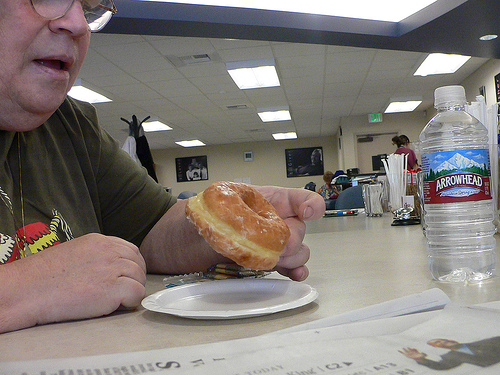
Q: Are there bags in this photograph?
A: No, there are no bags.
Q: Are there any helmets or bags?
A: No, there are no bags or helmets.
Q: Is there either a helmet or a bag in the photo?
A: No, there are no bags or helmets.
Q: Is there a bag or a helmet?
A: No, there are no bags or helmets.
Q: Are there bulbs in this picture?
A: No, there are no bulbs.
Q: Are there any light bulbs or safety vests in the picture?
A: No, there are no light bulbs or safety vests.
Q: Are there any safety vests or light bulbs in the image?
A: No, there are no light bulbs or safety vests.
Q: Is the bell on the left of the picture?
A: No, the bell is on the right of the image.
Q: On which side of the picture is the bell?
A: The bell is on the right of the image.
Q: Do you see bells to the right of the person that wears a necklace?
A: Yes, there is a bell to the right of the person.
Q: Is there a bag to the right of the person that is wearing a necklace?
A: No, there is a bell to the right of the person.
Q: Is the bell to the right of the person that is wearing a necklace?
A: Yes, the bell is to the right of the person.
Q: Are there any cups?
A: Yes, there is a cup.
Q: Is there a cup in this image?
A: Yes, there is a cup.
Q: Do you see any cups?
A: Yes, there is a cup.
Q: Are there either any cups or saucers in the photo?
A: Yes, there is a cup.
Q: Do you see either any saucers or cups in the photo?
A: Yes, there is a cup.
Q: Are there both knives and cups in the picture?
A: No, there is a cup but no knives.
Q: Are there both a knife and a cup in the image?
A: No, there is a cup but no knives.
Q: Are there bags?
A: No, there are no bags.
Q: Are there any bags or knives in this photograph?
A: No, there are no bags or knives.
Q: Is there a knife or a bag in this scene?
A: No, there are no bags or knives.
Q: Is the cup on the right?
A: Yes, the cup is on the right of the image.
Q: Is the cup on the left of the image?
A: No, the cup is on the right of the image.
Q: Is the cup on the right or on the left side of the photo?
A: The cup is on the right of the image.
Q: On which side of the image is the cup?
A: The cup is on the right of the image.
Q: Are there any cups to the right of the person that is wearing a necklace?
A: Yes, there is a cup to the right of the person.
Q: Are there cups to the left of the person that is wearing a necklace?
A: No, the cup is to the right of the person.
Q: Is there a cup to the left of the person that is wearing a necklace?
A: No, the cup is to the right of the person.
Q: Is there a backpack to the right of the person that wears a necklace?
A: No, there is a cup to the right of the person.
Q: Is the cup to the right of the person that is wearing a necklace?
A: Yes, the cup is to the right of the person.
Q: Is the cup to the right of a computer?
A: No, the cup is to the right of the person.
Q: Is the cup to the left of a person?
A: No, the cup is to the right of a person.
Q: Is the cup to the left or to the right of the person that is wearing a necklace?
A: The cup is to the right of the person.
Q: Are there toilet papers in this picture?
A: No, there are no toilet papers.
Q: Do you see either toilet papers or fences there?
A: No, there are no toilet papers or fences.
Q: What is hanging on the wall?
A: The poster is hanging on the wall.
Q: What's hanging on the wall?
A: The poster is hanging on the wall.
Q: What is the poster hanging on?
A: The poster is hanging on the wall.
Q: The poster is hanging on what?
A: The poster is hanging on the wall.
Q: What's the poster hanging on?
A: The poster is hanging on the wall.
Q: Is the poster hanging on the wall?
A: Yes, the poster is hanging on the wall.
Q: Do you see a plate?
A: Yes, there is a plate.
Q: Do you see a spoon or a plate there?
A: Yes, there is a plate.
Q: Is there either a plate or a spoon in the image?
A: Yes, there is a plate.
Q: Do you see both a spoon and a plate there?
A: No, there is a plate but no spoons.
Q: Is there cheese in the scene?
A: No, there is no cheese.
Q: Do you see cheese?
A: No, there is no cheese.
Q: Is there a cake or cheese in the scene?
A: No, there are no cheese or cakes.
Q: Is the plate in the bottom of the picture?
A: Yes, the plate is in the bottom of the image.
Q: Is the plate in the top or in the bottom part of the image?
A: The plate is in the bottom of the image.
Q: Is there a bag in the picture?
A: No, there are no bags.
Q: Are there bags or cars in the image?
A: No, there are no bags or cars.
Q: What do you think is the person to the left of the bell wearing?
A: The person is wearing a necklace.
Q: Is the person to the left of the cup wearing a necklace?
A: Yes, the person is wearing a necklace.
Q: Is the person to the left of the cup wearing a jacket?
A: No, the person is wearing a necklace.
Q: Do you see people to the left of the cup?
A: Yes, there is a person to the left of the cup.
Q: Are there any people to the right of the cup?
A: No, the person is to the left of the cup.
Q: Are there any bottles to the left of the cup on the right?
A: No, there is a person to the left of the cup.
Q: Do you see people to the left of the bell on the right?
A: Yes, there is a person to the left of the bell.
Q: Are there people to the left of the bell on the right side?
A: Yes, there is a person to the left of the bell.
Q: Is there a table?
A: Yes, there is a table.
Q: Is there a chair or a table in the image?
A: Yes, there is a table.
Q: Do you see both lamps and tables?
A: No, there is a table but no lamps.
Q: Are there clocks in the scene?
A: No, there are no clocks.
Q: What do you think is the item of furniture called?
A: The piece of furniture is a table.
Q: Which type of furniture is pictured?
A: The furniture is a table.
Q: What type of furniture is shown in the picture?
A: The furniture is a table.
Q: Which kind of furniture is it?
A: The piece of furniture is a table.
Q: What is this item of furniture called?
A: This is a table.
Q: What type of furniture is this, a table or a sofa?
A: This is a table.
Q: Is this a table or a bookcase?
A: This is a table.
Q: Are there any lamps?
A: No, there are no lamps.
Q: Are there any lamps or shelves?
A: No, there are no lamps or shelves.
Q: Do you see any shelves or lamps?
A: No, there are no lamps or shelves.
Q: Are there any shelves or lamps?
A: No, there are no lamps or shelves.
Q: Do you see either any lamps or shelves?
A: No, there are no lamps or shelves.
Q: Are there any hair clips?
A: No, there are no hair clips.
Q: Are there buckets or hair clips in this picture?
A: No, there are no hair clips or buckets.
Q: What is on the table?
A: The newspaper is on the table.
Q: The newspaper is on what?
A: The newspaper is on the table.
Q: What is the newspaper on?
A: The newspaper is on the table.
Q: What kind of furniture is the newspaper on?
A: The newspaper is on the table.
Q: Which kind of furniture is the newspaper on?
A: The newspaper is on the table.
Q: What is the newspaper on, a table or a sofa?
A: The newspaper is on a table.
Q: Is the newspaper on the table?
A: Yes, the newspaper is on the table.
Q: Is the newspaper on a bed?
A: No, the newspaper is on the table.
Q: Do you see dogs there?
A: No, there are no dogs.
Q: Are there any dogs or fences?
A: No, there are no dogs or fences.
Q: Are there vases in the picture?
A: No, there are no vases.